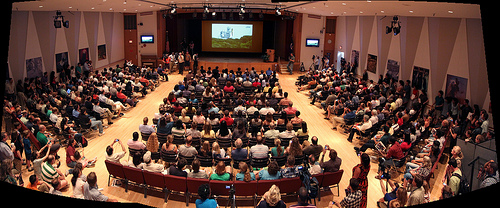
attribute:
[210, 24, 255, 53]
television — wall mounted, flat screen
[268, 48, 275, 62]
podium — brown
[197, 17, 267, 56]
screen — big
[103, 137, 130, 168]
person — taking a picture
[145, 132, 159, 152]
hair — long, curly, blonde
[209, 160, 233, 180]
woman — red haired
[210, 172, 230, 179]
shirt — green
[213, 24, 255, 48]
screen — movie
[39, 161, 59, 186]
shirt — white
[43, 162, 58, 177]
stripe — green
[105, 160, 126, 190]
seats — auditorium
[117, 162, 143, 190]
seats — auditorium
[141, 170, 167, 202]
seats — auditorium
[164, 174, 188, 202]
seats — auditorium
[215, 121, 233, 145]
woman — black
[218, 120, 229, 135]
hair — long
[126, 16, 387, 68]
screens — television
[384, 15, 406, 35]
light — big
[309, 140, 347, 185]
man — taking pictures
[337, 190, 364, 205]
shirt — white and black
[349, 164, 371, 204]
dress — red and black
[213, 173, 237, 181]
shirt — blue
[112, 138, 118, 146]
camera — digital